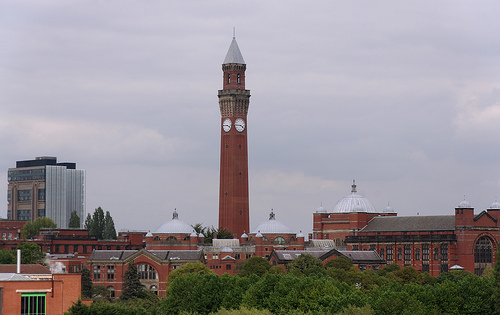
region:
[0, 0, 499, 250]
Overcast sky full of clouds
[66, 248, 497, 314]
Group of trees at forefront of photo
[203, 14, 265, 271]
Tall red tower in the middle of town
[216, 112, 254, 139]
Clocks in the face of tower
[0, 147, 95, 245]
Second tallest building in the photo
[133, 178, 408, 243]
White domed roofs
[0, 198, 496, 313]
Red bricj buildings without clock faces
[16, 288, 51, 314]
Green-framed window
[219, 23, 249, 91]
Lookout of tallest building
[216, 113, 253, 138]
Clocks showing 4:45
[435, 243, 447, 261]
window on side of building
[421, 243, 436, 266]
window on side of building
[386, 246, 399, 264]
window on side of building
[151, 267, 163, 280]
window on side of building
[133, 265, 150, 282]
window on side of building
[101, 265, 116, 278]
window on side of building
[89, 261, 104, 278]
window on side of building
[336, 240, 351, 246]
window on side of building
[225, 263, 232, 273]
window on side of building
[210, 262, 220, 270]
window on side of building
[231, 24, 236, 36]
Top of clock tower has a gray needle on it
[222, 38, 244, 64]
Roof of clock tower is gray and triangular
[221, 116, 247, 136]
Clock tower has two clocks on it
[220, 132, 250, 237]
Clock tower is made of red bricks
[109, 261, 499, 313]
Group of green leafy trees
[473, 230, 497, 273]
Front window of building is arched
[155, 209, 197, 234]
Top of building is dome shaped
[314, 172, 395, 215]
Four domes on top of building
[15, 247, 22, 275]
White pipe sticking up from roof of building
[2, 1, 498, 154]
Sky is very cloudy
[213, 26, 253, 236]
large clock tower in middle of the buildings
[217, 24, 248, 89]
top of the large clock tower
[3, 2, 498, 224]
grey sky behind clock tower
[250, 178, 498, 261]
buildings to the right of clock tower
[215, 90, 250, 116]
first tier of long clock tower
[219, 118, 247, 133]
clock area of long clock tower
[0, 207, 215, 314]
buildings to the left of long clock tower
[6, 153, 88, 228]
larger building on left of tower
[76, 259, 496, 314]
tops of large trees in front of buildings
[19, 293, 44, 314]
green window in building on left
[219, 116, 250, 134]
Two white faced clocks on a tall tower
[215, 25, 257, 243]
Tall brick tower with two clocks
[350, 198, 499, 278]
Red bricked cathedral styled building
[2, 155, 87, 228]
Yellow bricked older building in background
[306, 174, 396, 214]
Domed white roof with point at top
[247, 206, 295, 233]
Domed white roof with point at top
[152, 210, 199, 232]
Domed white roof with point at top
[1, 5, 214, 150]
Foggy white gray sky with clouds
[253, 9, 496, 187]
Foggy white gray sky with clouds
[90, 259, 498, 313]
Green trees and shrubs